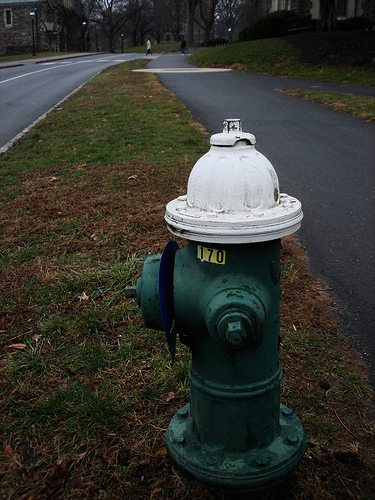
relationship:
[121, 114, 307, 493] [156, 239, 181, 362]
hydrant has disk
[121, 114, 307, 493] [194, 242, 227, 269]
hydrant has number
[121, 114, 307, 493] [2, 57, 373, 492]
hydrant on grass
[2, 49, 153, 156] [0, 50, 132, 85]
road has line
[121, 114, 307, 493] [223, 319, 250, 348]
hydrant has bolt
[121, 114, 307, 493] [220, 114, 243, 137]
hydrant has bolt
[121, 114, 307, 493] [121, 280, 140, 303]
hydrant has bolt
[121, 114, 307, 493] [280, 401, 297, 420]
hydrant has bolt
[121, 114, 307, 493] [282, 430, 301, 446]
hydrant has bolt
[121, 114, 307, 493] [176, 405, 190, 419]
hydrant has bolt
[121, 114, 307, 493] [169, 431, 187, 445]
hydrant has bolt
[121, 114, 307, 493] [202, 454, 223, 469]
hydrant has bolt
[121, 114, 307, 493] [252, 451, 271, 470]
hydrant has bolt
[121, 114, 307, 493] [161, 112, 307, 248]
hydrant has cap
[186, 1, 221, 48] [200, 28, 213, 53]
tree has trunk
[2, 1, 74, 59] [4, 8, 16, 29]
building has window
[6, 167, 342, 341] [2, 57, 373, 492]
dry grass on grass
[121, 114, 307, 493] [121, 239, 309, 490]
hydrant has base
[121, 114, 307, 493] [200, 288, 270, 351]
hydrant has plug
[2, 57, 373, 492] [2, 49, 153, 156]
grass by road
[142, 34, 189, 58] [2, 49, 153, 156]
people cross road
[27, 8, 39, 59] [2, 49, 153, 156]
lamp near road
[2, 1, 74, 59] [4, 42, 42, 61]
building has bushes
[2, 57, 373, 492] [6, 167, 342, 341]
grass has dry grass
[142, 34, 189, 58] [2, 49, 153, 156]
people on road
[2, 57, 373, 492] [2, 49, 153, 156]
grass near road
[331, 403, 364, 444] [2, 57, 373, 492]
twig on grass